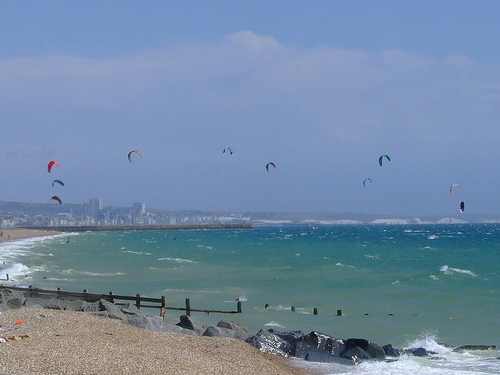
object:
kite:
[50, 179, 63, 190]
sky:
[0, 0, 498, 211]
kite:
[265, 161, 275, 172]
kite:
[459, 199, 466, 215]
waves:
[0, 229, 80, 287]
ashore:
[0, 226, 61, 243]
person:
[0, 333, 26, 343]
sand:
[1, 305, 305, 374]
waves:
[350, 335, 500, 375]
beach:
[0, 225, 350, 375]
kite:
[47, 159, 57, 174]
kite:
[49, 195, 63, 206]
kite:
[127, 148, 138, 163]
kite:
[220, 146, 234, 156]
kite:
[362, 176, 372, 188]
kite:
[378, 155, 392, 167]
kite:
[448, 183, 458, 197]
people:
[65, 235, 72, 243]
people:
[4, 234, 12, 239]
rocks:
[246, 328, 400, 366]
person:
[159, 307, 166, 318]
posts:
[0, 284, 191, 317]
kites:
[222, 145, 234, 155]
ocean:
[0, 220, 500, 375]